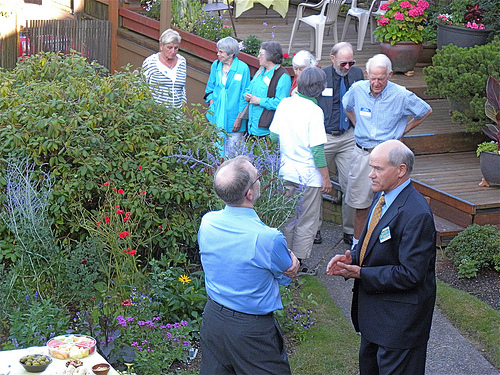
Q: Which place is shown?
A: It is a garden.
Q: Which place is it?
A: It is a garden.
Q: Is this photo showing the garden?
A: Yes, it is showing the garden.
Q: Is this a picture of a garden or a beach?
A: It is showing a garden.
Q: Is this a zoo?
A: No, it is a garden.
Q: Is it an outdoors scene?
A: Yes, it is outdoors.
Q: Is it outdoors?
A: Yes, it is outdoors.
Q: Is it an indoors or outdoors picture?
A: It is outdoors.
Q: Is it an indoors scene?
A: No, it is outdoors.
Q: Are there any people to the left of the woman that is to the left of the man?
A: Yes, there are people to the left of the woman.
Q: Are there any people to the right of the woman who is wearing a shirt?
A: No, the people are to the left of the woman.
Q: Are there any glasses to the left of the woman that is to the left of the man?
A: No, there are people to the left of the woman.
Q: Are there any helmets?
A: No, there are no helmets.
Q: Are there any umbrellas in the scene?
A: No, there are no umbrellas.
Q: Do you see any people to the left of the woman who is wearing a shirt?
A: Yes, there are people to the left of the woman.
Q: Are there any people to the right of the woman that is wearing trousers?
A: No, the people are to the left of the woman.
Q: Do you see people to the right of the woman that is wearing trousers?
A: No, the people are to the left of the woman.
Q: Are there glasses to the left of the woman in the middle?
A: No, there are people to the left of the woman.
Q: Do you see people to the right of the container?
A: Yes, there are people to the right of the container.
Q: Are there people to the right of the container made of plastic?
A: Yes, there are people to the right of the container.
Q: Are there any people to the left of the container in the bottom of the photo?
A: No, the people are to the right of the container.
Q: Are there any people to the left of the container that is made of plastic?
A: No, the people are to the right of the container.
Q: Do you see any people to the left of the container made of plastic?
A: No, the people are to the right of the container.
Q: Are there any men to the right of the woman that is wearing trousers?
A: Yes, there is a man to the right of the woman.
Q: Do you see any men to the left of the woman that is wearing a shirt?
A: No, the man is to the right of the woman.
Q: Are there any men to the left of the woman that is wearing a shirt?
A: No, the man is to the right of the woman.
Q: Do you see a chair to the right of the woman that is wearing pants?
A: No, there is a man to the right of the woman.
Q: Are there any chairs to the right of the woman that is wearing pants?
A: No, there is a man to the right of the woman.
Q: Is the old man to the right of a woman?
A: Yes, the man is to the right of a woman.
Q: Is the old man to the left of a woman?
A: No, the man is to the right of a woman.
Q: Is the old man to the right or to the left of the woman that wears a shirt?
A: The man is to the right of the woman.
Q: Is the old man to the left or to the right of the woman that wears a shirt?
A: The man is to the right of the woman.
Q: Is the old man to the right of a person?
A: Yes, the man is to the right of a person.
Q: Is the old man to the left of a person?
A: No, the man is to the right of a person.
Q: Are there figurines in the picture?
A: No, there are no figurines.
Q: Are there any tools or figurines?
A: No, there are no figurines or tools.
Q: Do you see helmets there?
A: No, there are no helmets.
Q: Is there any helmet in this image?
A: No, there are no helmets.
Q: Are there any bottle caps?
A: No, there are no bottle caps.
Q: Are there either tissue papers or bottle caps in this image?
A: No, there are no bottle caps or tissue papers.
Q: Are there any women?
A: Yes, there is a woman.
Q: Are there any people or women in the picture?
A: Yes, there is a woman.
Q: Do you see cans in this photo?
A: No, there are no cans.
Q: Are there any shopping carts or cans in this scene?
A: No, there are no cans or shopping carts.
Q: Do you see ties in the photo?
A: Yes, there is a tie.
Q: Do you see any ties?
A: Yes, there is a tie.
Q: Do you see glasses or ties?
A: Yes, there is a tie.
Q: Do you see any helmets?
A: No, there are no helmets.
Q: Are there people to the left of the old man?
A: Yes, there is a person to the left of the man.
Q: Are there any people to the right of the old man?
A: No, the person is to the left of the man.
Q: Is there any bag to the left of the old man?
A: No, there is a person to the left of the man.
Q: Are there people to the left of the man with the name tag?
A: Yes, there is a person to the left of the man.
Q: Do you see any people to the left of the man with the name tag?
A: Yes, there is a person to the left of the man.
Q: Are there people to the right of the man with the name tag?
A: No, the person is to the left of the man.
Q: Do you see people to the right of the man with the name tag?
A: No, the person is to the left of the man.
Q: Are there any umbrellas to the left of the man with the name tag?
A: No, there is a person to the left of the man.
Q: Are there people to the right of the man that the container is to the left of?
A: Yes, there is a person to the right of the man.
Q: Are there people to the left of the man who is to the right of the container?
A: No, the person is to the right of the man.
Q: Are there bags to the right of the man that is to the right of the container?
A: No, there is a person to the right of the man.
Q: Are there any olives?
A: Yes, there are olives.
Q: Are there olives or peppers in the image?
A: Yes, there are olives.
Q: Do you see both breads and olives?
A: No, there are olives but no breads.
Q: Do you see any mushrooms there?
A: No, there are no mushrooms.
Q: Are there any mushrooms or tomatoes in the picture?
A: No, there are no mushrooms or tomatoes.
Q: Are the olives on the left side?
A: Yes, the olives are on the left of the image.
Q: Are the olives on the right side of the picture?
A: No, the olives are on the left of the image.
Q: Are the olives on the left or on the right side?
A: The olives are on the left of the image.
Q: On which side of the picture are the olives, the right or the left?
A: The olives are on the left of the image.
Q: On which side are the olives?
A: The olives are on the left of the image.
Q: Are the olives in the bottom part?
A: Yes, the olives are in the bottom of the image.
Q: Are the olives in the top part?
A: No, the olives are in the bottom of the image.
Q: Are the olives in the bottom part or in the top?
A: The olives are in the bottom of the image.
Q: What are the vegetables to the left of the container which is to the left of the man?
A: The vegetables are olives.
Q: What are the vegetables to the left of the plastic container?
A: The vegetables are olives.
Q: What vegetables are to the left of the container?
A: The vegetables are olives.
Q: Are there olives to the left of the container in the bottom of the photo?
A: Yes, there are olives to the left of the container.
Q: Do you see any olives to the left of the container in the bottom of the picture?
A: Yes, there are olives to the left of the container.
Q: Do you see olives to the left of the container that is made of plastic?
A: Yes, there are olives to the left of the container.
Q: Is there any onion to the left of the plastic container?
A: No, there are olives to the left of the container.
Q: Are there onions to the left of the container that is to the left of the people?
A: No, there are olives to the left of the container.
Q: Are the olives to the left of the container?
A: Yes, the olives are to the left of the container.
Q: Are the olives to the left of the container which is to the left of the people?
A: Yes, the olives are to the left of the container.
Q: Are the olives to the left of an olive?
A: No, the olives are to the left of the container.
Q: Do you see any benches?
A: No, there are no benches.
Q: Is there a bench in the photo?
A: No, there are no benches.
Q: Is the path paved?
A: Yes, the path is paved.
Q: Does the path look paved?
A: Yes, the path is paved.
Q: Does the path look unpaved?
A: No, the path is paved.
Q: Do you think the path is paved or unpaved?
A: The path is paved.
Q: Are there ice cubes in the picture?
A: No, there are no ice cubes.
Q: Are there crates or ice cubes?
A: No, there are no ice cubes or crates.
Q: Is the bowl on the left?
A: Yes, the bowl is on the left of the image.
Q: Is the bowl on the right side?
A: No, the bowl is on the left of the image.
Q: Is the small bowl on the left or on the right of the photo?
A: The bowl is on the left of the image.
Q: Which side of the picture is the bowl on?
A: The bowl is on the left of the image.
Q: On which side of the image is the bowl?
A: The bowl is on the left of the image.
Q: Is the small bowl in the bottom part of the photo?
A: Yes, the bowl is in the bottom of the image.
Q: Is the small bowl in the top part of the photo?
A: No, the bowl is in the bottom of the image.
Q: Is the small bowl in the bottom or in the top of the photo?
A: The bowl is in the bottom of the image.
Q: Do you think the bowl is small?
A: Yes, the bowl is small.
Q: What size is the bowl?
A: The bowl is small.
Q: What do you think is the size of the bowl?
A: The bowl is small.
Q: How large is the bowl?
A: The bowl is small.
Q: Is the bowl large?
A: No, the bowl is small.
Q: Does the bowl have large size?
A: No, the bowl is small.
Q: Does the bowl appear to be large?
A: No, the bowl is small.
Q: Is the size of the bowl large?
A: No, the bowl is small.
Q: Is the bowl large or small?
A: The bowl is small.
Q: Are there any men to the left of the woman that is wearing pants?
A: No, the man is to the right of the woman.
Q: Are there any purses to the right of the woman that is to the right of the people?
A: No, there is a man to the right of the woman.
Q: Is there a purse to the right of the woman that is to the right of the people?
A: No, there is a man to the right of the woman.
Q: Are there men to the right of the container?
A: Yes, there is a man to the right of the container.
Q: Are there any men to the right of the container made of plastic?
A: Yes, there is a man to the right of the container.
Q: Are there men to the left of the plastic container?
A: No, the man is to the right of the container.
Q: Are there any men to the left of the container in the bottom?
A: No, the man is to the right of the container.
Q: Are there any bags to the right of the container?
A: No, there is a man to the right of the container.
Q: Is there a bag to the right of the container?
A: No, there is a man to the right of the container.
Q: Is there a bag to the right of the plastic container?
A: No, there is a man to the right of the container.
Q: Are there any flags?
A: No, there are no flags.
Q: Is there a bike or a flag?
A: No, there are no flags or bikes.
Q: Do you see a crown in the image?
A: No, there are no crowns.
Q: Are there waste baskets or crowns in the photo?
A: No, there are no crowns or waste baskets.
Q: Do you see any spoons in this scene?
A: No, there are no spoons.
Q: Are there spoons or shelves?
A: No, there are no spoons or shelves.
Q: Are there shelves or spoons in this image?
A: No, there are no spoons or shelves.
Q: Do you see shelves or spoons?
A: No, there are no spoons or shelves.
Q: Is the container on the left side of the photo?
A: Yes, the container is on the left of the image.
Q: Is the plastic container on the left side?
A: Yes, the container is on the left of the image.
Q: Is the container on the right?
A: No, the container is on the left of the image.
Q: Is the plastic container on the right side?
A: No, the container is on the left of the image.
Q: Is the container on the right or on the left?
A: The container is on the left of the image.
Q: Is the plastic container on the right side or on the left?
A: The container is on the left of the image.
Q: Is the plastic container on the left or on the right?
A: The container is on the left of the image.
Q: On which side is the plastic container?
A: The container is on the left of the image.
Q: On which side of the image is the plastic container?
A: The container is on the left of the image.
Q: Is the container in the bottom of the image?
A: Yes, the container is in the bottom of the image.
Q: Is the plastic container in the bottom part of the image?
A: Yes, the container is in the bottom of the image.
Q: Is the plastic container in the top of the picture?
A: No, the container is in the bottom of the image.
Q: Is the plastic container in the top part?
A: No, the container is in the bottom of the image.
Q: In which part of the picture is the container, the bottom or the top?
A: The container is in the bottom of the image.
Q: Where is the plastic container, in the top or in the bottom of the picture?
A: The container is in the bottom of the image.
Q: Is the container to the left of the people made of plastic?
A: Yes, the container is made of plastic.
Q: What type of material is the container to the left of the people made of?
A: The container is made of plastic.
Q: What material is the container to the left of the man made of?
A: The container is made of plastic.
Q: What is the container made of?
A: The container is made of plastic.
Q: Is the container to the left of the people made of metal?
A: No, the container is made of plastic.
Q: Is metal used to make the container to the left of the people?
A: No, the container is made of plastic.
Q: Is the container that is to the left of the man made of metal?
A: No, the container is made of plastic.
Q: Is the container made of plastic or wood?
A: The container is made of plastic.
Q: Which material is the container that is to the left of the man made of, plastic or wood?
A: The container is made of plastic.